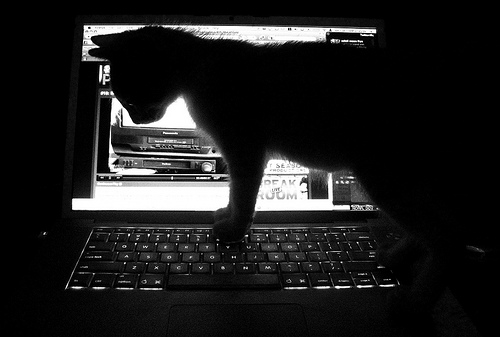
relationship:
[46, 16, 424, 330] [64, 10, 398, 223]
laptop has monitor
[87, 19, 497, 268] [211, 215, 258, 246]
cat has left paw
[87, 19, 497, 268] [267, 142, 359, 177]
cat has stomach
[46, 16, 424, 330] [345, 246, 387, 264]
laptop has button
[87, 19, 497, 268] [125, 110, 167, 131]
cat has mouth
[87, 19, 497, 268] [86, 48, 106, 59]
cat has ear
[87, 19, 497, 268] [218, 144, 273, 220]
cat has leg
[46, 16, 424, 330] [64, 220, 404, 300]
laptop has keyboard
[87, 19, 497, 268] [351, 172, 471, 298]
cat has hind leg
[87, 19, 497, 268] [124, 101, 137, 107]
cat has eye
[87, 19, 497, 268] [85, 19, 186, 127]
cat has head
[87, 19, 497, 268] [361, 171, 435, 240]
cat has leg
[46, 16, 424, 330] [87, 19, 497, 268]
laptop illuminates cat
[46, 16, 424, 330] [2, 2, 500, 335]
laptop in room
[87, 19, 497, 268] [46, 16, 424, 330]
cat on laptop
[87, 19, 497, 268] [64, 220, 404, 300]
cat on keyboard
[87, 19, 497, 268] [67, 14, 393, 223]
cat in front of screen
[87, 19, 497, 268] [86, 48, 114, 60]
cat has ear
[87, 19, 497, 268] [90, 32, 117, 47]
cat has ear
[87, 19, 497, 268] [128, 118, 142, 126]
cat has nose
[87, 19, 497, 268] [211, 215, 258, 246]
cat has paw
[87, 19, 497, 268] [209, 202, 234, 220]
cat has paw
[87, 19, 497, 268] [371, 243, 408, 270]
cat has paw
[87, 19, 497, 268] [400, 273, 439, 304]
cat has paw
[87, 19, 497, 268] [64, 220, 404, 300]
cat uses keyboard